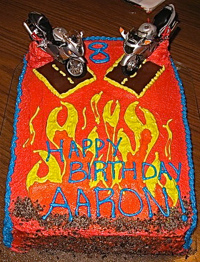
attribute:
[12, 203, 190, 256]
stuff — brown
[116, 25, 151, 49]
mirrors — orange, white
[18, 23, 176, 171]
cake — birthday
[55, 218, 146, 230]
sprinkles — chocolate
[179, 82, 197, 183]
icing — bright blue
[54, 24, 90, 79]
toy — handle bar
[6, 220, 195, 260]
cake side — brown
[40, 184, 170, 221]
aaron — bright blue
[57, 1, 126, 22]
plywood/table — plywood, wooden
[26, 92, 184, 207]
yellow frosting — decorative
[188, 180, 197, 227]
edging — blue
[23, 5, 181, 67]
motorcycles — toy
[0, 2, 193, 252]
cake — cream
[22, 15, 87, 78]
toy motorcycle — silver